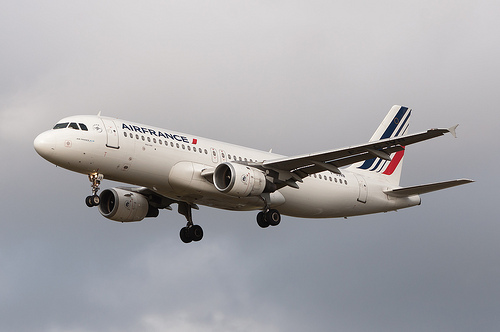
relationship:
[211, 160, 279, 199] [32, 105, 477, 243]
engine of a airplane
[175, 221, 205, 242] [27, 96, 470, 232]
left wheels of a plane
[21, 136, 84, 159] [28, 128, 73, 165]
nose of a plane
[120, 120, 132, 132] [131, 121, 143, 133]
letter on a letter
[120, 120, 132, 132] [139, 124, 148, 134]
letter on a letter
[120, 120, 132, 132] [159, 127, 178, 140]
letter on a letter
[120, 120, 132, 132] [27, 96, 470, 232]
letter on a plane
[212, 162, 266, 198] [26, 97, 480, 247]
engine on airplane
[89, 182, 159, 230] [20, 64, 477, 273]
engine on airplane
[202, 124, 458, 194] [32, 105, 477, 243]
wing of airplane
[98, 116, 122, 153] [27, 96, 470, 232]
door on plane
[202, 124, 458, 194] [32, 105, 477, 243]
wing on airplane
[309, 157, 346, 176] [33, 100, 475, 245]
slat under wing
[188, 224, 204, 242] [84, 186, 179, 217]
left wheels under wing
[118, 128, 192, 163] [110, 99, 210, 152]
window under logo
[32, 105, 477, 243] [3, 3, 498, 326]
airplane in sky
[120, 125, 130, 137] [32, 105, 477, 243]
window on airplane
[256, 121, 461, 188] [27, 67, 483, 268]
wing on jet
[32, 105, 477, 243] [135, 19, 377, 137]
airplane in sky